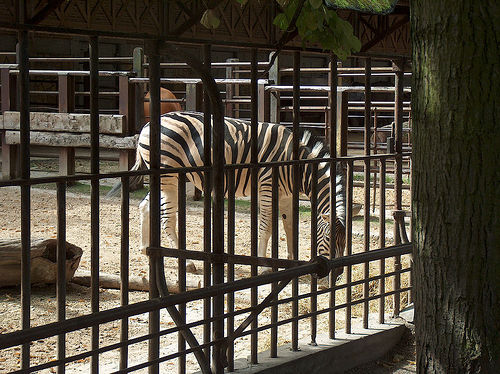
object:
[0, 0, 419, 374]
bars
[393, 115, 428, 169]
ground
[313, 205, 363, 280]
head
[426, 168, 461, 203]
ground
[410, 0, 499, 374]
log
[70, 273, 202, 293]
log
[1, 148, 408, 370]
ground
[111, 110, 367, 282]
hydrant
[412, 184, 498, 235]
treebark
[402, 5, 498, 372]
tree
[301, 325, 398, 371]
curb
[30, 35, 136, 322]
water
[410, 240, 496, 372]
tree trunk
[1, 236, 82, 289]
log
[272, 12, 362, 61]
leaves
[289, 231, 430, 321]
hay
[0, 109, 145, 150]
slats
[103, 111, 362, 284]
zebra